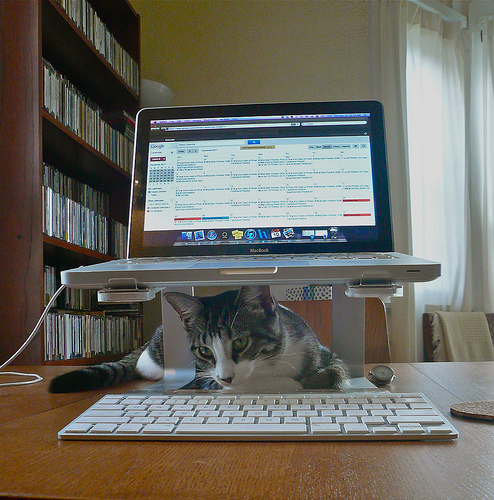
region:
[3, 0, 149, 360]
a book shelf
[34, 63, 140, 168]
books on the shelf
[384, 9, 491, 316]
a white curtain on the windows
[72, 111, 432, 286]
a laptop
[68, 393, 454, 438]
a white keyboard on the desk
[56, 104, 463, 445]
a computer on a desk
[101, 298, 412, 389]
a cat laying on the desk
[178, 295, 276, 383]
the face of the cat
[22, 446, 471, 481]
the desk under the computer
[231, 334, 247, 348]
the eye of the cat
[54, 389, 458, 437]
Thin white computer keyboard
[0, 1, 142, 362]
Wooden bookshelf filled with books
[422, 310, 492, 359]
Cream colored blanket draped over chair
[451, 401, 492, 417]
Cork beverage coaster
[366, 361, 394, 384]
Polished silver watch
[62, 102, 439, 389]
Macbook sitting on metal stand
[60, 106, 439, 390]
Green eyed cat sitting underneath laptop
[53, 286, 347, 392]
Brown and white cat with striped tail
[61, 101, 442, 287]
Open laptop using Google calendar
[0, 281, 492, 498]
Cat sitting on top of wooden desk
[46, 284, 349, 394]
a black, white, and gray cat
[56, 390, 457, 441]
a white keyboard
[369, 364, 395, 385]
a watch with a white face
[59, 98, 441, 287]
a white colored laptop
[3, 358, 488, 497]
a brown wooden table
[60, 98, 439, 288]
a MacBook laptop computer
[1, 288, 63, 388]
a gray colored cord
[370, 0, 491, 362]
a long white curtain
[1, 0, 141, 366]
a brown wooden shelf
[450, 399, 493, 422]
a pressed wood coaster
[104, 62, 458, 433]
the cat is holding the laptop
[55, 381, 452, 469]
the keyboard is on the desk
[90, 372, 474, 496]
the keyboard is white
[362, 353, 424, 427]
the watch is on the desk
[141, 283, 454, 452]
the cat is underneath the laptop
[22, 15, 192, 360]
a bookshelf is full of books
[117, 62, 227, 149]
a lamp is in the corner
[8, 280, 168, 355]
a cord is connected to the computer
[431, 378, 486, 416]
a coaster is on the table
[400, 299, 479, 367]
the sweater is on the chair